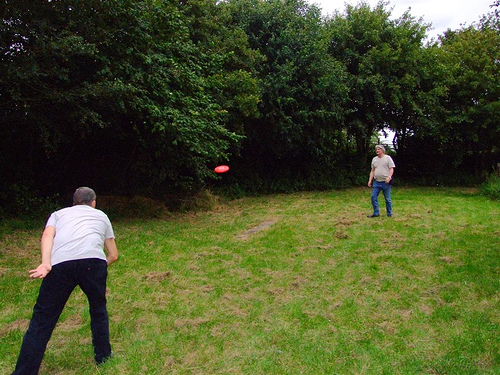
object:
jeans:
[371, 181, 393, 216]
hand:
[29, 263, 52, 279]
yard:
[4, 174, 499, 373]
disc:
[214, 165, 230, 174]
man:
[11, 186, 118, 375]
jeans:
[12, 259, 112, 374]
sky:
[299, 1, 498, 51]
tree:
[318, 0, 431, 182]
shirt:
[46, 205, 117, 267]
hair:
[375, 144, 385, 153]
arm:
[41, 213, 56, 264]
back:
[53, 206, 105, 261]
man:
[366, 145, 396, 218]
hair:
[73, 187, 97, 206]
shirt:
[371, 154, 396, 182]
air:
[314, 0, 480, 25]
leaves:
[5, 3, 476, 155]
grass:
[0, 196, 500, 375]